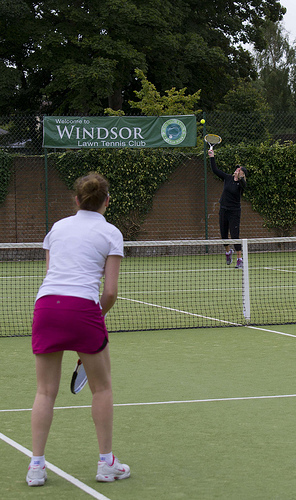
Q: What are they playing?
A: Tennis.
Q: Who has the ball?
A: The woman in black.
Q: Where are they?
A: At the Windsor Lawn Tennis Club.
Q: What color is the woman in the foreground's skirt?
A: Pink.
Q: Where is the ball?
A: Just about the woman in black's racket.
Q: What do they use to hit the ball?
A: Tennis rackets.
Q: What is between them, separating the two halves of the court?
A: A net.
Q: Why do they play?
A: For fun.